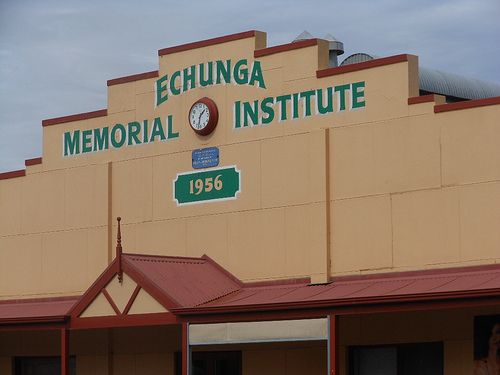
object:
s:
[256, 95, 275, 124]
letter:
[60, 129, 82, 156]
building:
[0, 31, 499, 371]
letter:
[231, 59, 249, 85]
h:
[181, 65, 196, 90]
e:
[153, 75, 168, 106]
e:
[81, 129, 92, 152]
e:
[350, 81, 365, 109]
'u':
[196, 59, 213, 86]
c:
[169, 69, 182, 96]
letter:
[77, 129, 93, 154]